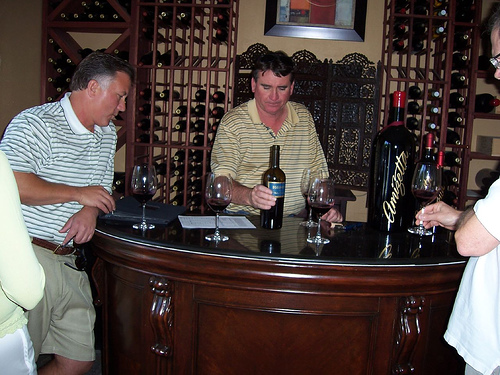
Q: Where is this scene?
A: A bar.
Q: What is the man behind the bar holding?
A: A bottle.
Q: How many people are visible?
A: Four.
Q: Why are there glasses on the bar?
A: They are holding wine for the men to drink.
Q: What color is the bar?
A: Brown.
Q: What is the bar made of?
A: Wood.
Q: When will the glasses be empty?
A: When the men finish drinking.